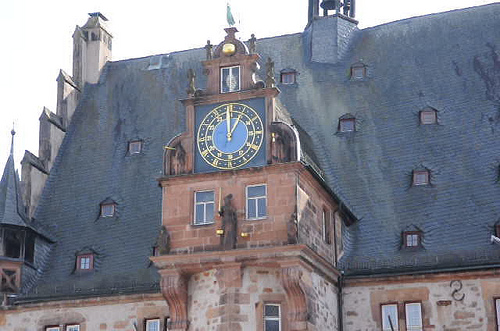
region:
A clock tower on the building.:
[155, 31, 350, 328]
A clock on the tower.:
[196, 98, 263, 165]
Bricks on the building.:
[202, 275, 250, 325]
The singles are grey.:
[70, 116, 115, 191]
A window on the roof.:
[71, 242, 97, 277]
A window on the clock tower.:
[240, 175, 274, 227]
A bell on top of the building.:
[305, 0, 356, 51]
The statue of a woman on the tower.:
[210, 190, 250, 250]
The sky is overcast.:
[11, 47, 51, 92]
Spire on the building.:
[1, 125, 28, 225]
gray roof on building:
[0, 2, 498, 301]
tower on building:
[156, 26, 344, 329]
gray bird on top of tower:
[223, 0, 239, 26]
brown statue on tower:
[217, 193, 239, 246]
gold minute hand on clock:
[225, 106, 232, 141]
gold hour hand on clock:
[229, 117, 241, 137]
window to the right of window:
[245, 183, 267, 218]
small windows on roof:
[411, 172, 429, 185]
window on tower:
[262, 302, 280, 329]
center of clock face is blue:
[213, 118, 245, 149]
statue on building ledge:
[209, 183, 247, 258]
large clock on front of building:
[177, 70, 277, 172]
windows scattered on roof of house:
[65, 105, 150, 287]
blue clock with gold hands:
[192, 95, 269, 170]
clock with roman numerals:
[191, 88, 270, 170]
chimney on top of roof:
[299, 0, 358, 61]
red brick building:
[182, 174, 333, 323]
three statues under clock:
[150, 188, 307, 263]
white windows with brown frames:
[370, 295, 432, 326]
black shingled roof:
[393, 43, 474, 99]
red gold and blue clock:
[192, 100, 267, 171]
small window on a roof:
[72, 245, 97, 272]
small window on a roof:
[95, 196, 118, 216]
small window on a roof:
[125, 138, 143, 155]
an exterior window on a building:
[192, 189, 214, 224]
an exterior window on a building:
[245, 183, 267, 219]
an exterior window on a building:
[265, 303, 282, 329]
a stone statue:
[216, 194, 240, 245]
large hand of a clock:
[225, 105, 232, 140]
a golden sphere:
[222, 41, 234, 58]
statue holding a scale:
[212, 191, 249, 251]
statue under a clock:
[192, 100, 267, 249]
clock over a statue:
[187, 96, 268, 255]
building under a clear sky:
[0, 2, 499, 330]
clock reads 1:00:
[192, 96, 272, 173]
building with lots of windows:
[0, 3, 499, 330]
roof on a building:
[3, 0, 495, 330]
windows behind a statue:
[190, 181, 271, 256]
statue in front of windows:
[183, 183, 274, 246]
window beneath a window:
[64, 190, 124, 279]